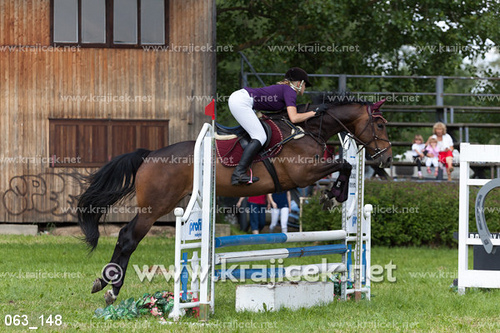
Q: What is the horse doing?
A: Jumping a hurdle.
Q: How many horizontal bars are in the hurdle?
A: Three.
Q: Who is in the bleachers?
A: A woman and two children.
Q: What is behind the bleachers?
A: Trees.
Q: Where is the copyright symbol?
A: Just above the horse's back hooves.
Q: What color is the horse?
A: Brown.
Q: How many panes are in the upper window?
A: Four.